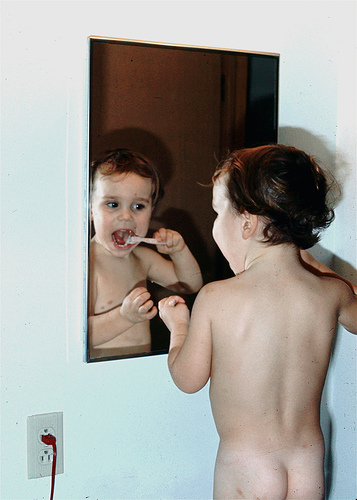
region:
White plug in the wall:
[24, 413, 70, 475]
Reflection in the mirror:
[91, 319, 123, 359]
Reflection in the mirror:
[117, 270, 152, 321]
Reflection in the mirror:
[149, 270, 201, 317]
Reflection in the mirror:
[143, 213, 186, 281]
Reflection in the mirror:
[93, 127, 130, 185]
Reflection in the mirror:
[127, 126, 173, 197]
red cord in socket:
[39, 433, 59, 446]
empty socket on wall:
[39, 452, 51, 466]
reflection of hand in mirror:
[121, 287, 153, 326]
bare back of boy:
[253, 316, 312, 405]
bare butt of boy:
[206, 452, 349, 497]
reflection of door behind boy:
[133, 106, 193, 142]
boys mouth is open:
[104, 225, 140, 254]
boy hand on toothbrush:
[151, 226, 189, 259]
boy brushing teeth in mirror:
[80, 95, 354, 373]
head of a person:
[198, 145, 323, 282]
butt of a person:
[225, 437, 327, 496]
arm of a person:
[174, 328, 220, 408]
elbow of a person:
[181, 385, 196, 396]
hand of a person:
[157, 296, 194, 326]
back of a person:
[216, 290, 336, 420]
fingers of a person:
[147, 293, 191, 314]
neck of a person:
[236, 239, 301, 277]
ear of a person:
[234, 204, 262, 238]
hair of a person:
[244, 151, 315, 217]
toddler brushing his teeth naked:
[22, 23, 330, 482]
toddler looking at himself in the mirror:
[88, 153, 329, 486]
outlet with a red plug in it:
[20, 408, 64, 483]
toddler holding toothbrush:
[118, 233, 166, 242]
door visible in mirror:
[85, 33, 247, 348]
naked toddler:
[167, 150, 334, 497]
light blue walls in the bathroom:
[8, 4, 351, 494]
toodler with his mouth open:
[108, 224, 133, 246]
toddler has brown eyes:
[100, 196, 143, 210]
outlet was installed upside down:
[27, 417, 62, 477]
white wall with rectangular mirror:
[3, 3, 347, 489]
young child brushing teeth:
[89, 126, 196, 354]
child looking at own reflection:
[89, 144, 153, 251]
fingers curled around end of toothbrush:
[122, 222, 180, 251]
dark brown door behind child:
[87, 32, 254, 347]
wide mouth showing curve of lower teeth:
[105, 218, 136, 250]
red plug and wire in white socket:
[27, 411, 58, 495]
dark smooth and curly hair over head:
[207, 132, 333, 248]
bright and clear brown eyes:
[99, 193, 143, 207]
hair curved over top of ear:
[233, 196, 260, 237]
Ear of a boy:
[238, 209, 263, 240]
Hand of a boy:
[153, 294, 191, 328]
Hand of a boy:
[150, 293, 192, 332]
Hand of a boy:
[156, 292, 196, 331]